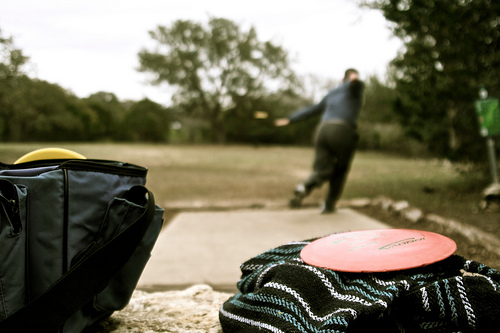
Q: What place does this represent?
A: It represents the field.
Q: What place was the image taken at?
A: It was taken at the field.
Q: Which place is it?
A: It is a field.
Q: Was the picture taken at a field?
A: Yes, it was taken in a field.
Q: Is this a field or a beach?
A: It is a field.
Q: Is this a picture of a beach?
A: No, the picture is showing a field.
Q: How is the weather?
A: It is cloudy.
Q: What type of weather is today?
A: It is cloudy.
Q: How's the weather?
A: It is cloudy.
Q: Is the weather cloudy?
A: Yes, it is cloudy.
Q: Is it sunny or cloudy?
A: It is cloudy.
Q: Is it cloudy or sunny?
A: It is cloudy.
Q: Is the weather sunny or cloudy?
A: It is cloudy.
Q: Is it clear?
A: No, it is cloudy.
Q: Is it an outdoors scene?
A: Yes, it is outdoors.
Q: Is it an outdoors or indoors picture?
A: It is outdoors.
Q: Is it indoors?
A: No, it is outdoors.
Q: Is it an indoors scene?
A: No, it is outdoors.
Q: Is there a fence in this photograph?
A: No, there are no fences.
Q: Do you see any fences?
A: No, there are no fences.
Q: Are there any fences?
A: No, there are no fences.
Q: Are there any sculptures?
A: No, there are no sculptures.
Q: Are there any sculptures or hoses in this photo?
A: No, there are no sculptures or hoses.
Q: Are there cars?
A: No, there are no cars.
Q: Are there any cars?
A: No, there are no cars.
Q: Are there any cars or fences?
A: No, there are no cars or fences.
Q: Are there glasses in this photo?
A: No, there are no glasses.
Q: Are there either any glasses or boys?
A: No, there are no glasses or boys.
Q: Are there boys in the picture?
A: No, there are no boys.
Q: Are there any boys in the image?
A: No, there are no boys.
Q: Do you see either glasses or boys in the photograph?
A: No, there are no boys or glasses.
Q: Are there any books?
A: No, there are no books.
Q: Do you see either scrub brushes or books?
A: No, there are no books or scrub brushes.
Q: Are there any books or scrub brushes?
A: No, there are no books or scrub brushes.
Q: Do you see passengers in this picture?
A: No, there are no passengers.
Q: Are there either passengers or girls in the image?
A: No, there are no passengers or girls.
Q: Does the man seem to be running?
A: Yes, the man is running.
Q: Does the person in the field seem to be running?
A: Yes, the man is running.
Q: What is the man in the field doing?
A: The man is running.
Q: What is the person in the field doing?
A: The man is running.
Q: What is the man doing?
A: The man is running.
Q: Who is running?
A: The man is running.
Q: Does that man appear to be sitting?
A: No, the man is running.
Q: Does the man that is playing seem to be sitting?
A: No, the man is running.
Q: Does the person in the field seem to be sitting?
A: No, the man is running.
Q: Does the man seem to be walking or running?
A: The man is running.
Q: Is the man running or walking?
A: The man is running.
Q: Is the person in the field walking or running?
A: The man is running.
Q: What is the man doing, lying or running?
A: The man is running.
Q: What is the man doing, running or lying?
A: The man is running.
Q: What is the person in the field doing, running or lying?
A: The man is running.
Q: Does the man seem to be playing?
A: Yes, the man is playing.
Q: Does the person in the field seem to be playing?
A: Yes, the man is playing.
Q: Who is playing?
A: The man is playing.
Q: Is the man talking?
A: No, the man is playing.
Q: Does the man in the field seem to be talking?
A: No, the man is playing.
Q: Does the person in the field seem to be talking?
A: No, the man is playing.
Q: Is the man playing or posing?
A: The man is playing.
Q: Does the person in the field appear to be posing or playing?
A: The man is playing.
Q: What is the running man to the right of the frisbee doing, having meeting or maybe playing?
A: The man is playing.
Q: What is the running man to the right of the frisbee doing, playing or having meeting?
A: The man is playing.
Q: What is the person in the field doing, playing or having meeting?
A: The man is playing.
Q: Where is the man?
A: The man is in the field.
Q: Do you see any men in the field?
A: Yes, there is a man in the field.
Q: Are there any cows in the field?
A: No, there is a man in the field.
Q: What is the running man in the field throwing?
A: The man is throwing the frisbee.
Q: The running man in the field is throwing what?
A: The man is throwing the frisbee.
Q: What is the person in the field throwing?
A: The man is throwing the frisbee.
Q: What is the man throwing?
A: The man is throwing the frisbee.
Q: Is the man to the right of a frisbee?
A: Yes, the man is to the right of a frisbee.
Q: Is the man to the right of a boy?
A: No, the man is to the right of a frisbee.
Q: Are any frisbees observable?
A: Yes, there is a frisbee.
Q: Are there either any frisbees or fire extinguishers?
A: Yes, there is a frisbee.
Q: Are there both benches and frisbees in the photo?
A: No, there is a frisbee but no benches.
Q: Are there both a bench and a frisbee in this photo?
A: No, there is a frisbee but no benches.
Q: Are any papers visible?
A: No, there are no papers.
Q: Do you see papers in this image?
A: No, there are no papers.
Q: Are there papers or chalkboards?
A: No, there are no papers or chalkboards.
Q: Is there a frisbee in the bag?
A: Yes, there is a frisbee in the bag.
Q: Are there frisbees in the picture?
A: Yes, there is a frisbee.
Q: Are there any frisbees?
A: Yes, there is a frisbee.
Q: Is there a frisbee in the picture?
A: Yes, there is a frisbee.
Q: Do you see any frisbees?
A: Yes, there is a frisbee.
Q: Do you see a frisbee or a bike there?
A: Yes, there is a frisbee.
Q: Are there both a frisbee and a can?
A: No, there is a frisbee but no cans.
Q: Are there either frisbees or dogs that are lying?
A: Yes, the frisbee is lying.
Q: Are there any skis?
A: No, there are no skis.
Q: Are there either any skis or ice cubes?
A: No, there are no skis or ice cubes.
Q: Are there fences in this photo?
A: No, there are no fences.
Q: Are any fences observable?
A: No, there are no fences.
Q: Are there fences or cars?
A: No, there are no fences or cars.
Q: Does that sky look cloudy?
A: Yes, the sky is cloudy.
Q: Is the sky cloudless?
A: No, the sky is cloudy.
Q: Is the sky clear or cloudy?
A: The sky is cloudy.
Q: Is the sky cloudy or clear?
A: The sky is cloudy.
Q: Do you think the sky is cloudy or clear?
A: The sky is cloudy.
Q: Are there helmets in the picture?
A: No, there are no helmets.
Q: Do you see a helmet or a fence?
A: No, there are no helmets or fences.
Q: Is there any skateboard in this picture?
A: No, there are no skateboards.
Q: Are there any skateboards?
A: No, there are no skateboards.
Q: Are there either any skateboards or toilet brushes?
A: No, there are no skateboards or toilet brushes.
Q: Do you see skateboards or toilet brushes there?
A: No, there are no skateboards or toilet brushes.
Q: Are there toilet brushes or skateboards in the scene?
A: No, there are no skateboards or toilet brushes.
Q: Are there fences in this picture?
A: No, there are no fences.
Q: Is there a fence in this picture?
A: No, there are no fences.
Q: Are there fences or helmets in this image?
A: No, there are no fences or helmets.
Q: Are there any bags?
A: Yes, there is a bag.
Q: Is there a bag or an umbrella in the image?
A: Yes, there is a bag.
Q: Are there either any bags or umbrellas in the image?
A: Yes, there is a bag.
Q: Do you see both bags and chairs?
A: No, there is a bag but no chairs.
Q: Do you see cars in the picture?
A: No, there are no cars.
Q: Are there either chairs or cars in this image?
A: No, there are no cars or chairs.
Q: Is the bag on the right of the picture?
A: No, the bag is on the left of the image.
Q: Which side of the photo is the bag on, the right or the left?
A: The bag is on the left of the image.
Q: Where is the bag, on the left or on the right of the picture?
A: The bag is on the left of the image.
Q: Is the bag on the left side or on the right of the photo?
A: The bag is on the left of the image.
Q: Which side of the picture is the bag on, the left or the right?
A: The bag is on the left of the image.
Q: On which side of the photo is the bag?
A: The bag is on the left of the image.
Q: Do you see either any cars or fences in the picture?
A: No, there are no fences or cars.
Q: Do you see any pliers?
A: No, there are no pliers.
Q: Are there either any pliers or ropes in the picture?
A: No, there are no pliers or ropes.